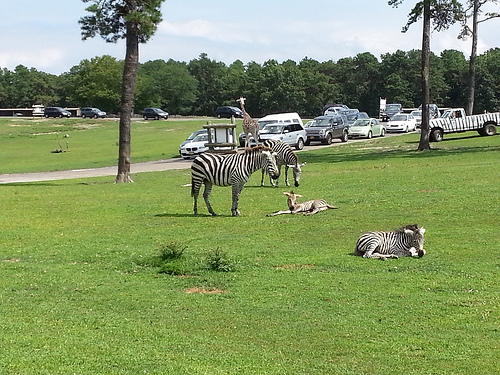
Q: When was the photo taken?
A: Daytime.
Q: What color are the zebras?
A: Black and white.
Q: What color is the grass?
A: Green.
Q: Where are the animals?
A: In the grass.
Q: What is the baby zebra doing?
A: Laying down.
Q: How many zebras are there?
A: Four.